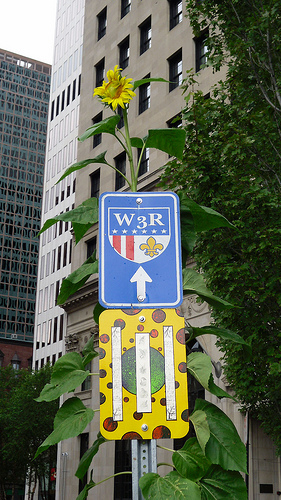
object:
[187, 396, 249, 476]
leaf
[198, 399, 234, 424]
edge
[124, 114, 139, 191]
stalk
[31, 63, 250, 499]
plant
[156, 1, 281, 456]
tree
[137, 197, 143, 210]
bolt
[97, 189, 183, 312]
sign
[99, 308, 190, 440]
sign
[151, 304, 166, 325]
circles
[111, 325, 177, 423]
stripes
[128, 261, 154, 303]
arrow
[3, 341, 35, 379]
bricks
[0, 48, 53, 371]
building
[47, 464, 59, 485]
sign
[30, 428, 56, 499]
window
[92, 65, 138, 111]
flower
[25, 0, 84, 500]
building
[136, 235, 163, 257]
fur de les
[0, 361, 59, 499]
tree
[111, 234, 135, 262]
flag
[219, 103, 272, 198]
leaves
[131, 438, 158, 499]
pole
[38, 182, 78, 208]
window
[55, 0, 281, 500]
building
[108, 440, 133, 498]
door